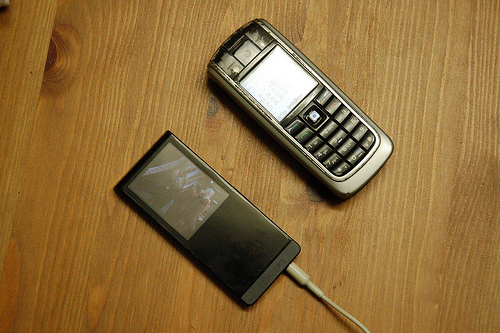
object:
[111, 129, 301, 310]
ipod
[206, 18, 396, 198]
electronic devices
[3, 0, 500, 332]
table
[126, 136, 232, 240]
screen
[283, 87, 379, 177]
keyboard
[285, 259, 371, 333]
charger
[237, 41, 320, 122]
screen